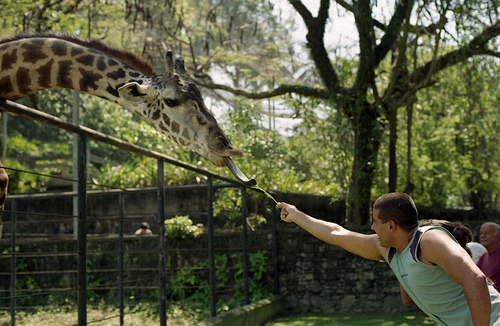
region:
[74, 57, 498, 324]
man gives something to eat to giraffe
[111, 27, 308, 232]
giraffe is reaching something with tongue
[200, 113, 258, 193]
big tongue of giraffe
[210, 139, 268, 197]
tongue of giraffe is black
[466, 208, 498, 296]
old man wears pink shirt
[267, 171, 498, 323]
man has short hair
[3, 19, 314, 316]
a giraffe behind a fence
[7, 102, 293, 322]
fence of metal is black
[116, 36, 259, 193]
tips of horns of giraffe are black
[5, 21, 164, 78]
mane of giraffe is brown and short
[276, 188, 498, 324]
excited man reaching up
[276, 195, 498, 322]
people standing beside each other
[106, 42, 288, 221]
a giraffe licking a leaf in someone's hand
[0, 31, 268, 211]
a giraffe leaning over a fence with its tongue out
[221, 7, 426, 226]
big mossy tree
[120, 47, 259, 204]
giraffe face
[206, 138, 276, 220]
giraffe tongue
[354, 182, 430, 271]
man's excited face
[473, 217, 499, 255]
man with white hair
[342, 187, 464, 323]
man in grey tank top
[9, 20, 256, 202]
a giraffe in a zoo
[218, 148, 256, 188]
long tongue of a giraffe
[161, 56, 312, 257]
man feeling a giraffe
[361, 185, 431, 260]
man with a buzz cut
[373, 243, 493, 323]
man wearing a pale green shirt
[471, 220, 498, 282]
old man wearing a magenta shirt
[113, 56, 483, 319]
man leaning in to feed a giraffe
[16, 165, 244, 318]
a black metal fence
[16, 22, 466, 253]
a giraffe being fed by a man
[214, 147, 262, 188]
a giraffe's tongue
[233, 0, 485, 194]
a beautiful tree.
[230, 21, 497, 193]
a bunch of green trees.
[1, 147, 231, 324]
a black cage.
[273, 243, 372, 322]
a grey and black brick wall.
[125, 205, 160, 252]
a man is looking on the ledge.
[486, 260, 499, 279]
a man is wearing a pink shirt.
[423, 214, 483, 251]
a man has a brown back pack.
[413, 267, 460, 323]
a man is wearing a green shirt.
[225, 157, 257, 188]
the giraffe has a long black tongue.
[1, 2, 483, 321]
a man is feeding a giraffe.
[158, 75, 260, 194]
Giraffe's tongue is sticking out.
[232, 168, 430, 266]
Boy trying to feed giraffe.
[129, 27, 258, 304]
Wire fence enclosing giraffe compound.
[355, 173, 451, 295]
Boy wearing light colored, sleeveless shirt.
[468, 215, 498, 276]
Older gentleman looking ahead.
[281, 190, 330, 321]
Stone wall on property.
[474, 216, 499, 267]
Gray hair on elderly man.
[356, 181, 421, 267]
Short haircut on boy.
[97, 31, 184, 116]
Dark spots on giraffe.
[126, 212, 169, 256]
Person standing on other side of fence.